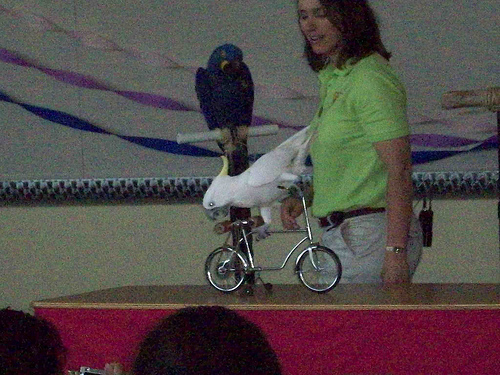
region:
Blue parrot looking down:
[191, 43, 259, 176]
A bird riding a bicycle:
[198, 121, 345, 296]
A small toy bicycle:
[206, 190, 345, 299]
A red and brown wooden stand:
[35, 281, 497, 371]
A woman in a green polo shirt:
[280, 1, 427, 282]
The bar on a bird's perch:
[173, 125, 285, 145]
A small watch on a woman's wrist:
[381, 241, 405, 256]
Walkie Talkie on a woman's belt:
[417, 192, 435, 249]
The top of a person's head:
[131, 303, 278, 373]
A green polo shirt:
[310, 58, 415, 221]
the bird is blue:
[213, 85, 232, 108]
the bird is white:
[243, 176, 271, 195]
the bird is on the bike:
[215, 179, 325, 260]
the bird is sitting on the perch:
[204, 106, 263, 143]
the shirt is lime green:
[321, 112, 364, 157]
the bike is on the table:
[217, 281, 345, 304]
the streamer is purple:
[113, 82, 149, 108]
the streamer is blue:
[116, 123, 163, 154]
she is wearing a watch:
[380, 240, 411, 260]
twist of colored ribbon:
[65, 16, 124, 57]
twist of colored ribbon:
[123, 38, 180, 77]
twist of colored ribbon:
[413, 108, 457, 133]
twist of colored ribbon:
[443, 109, 498, 139]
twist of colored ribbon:
[0, 42, 47, 75]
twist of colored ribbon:
[42, 56, 114, 99]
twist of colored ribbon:
[120, 82, 197, 124]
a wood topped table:
[28, 279, 495, 309]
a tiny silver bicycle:
[195, 172, 347, 296]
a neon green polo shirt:
[306, 69, 421, 216]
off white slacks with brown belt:
[301, 199, 428, 290]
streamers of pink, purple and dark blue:
[3, 0, 199, 162]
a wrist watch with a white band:
[381, 242, 408, 257]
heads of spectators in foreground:
[1, 297, 276, 373]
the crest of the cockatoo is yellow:
[208, 147, 236, 180]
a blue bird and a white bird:
[178, 33, 321, 250]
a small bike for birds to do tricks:
[202, 208, 351, 305]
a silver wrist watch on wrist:
[373, 243, 418, 263]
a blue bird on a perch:
[168, 41, 282, 159]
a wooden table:
[63, 265, 495, 316]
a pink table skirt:
[62, 305, 498, 368]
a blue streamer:
[6, 88, 173, 157]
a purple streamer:
[8, 49, 207, 124]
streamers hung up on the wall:
[26, 32, 187, 185]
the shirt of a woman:
[305, 61, 410, 209]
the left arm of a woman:
[348, 92, 419, 286]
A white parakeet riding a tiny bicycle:
[196, 115, 351, 300]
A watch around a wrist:
[375, 235, 412, 261]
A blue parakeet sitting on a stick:
[182, 30, 259, 182]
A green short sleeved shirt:
[300, 46, 416, 223]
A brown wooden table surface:
[26, 275, 496, 317]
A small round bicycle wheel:
[285, 237, 350, 297]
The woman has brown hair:
[290, 0, 397, 75]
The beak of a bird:
[197, 191, 237, 223]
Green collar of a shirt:
[310, 51, 360, 86]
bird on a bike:
[198, 109, 343, 299]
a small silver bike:
[200, 165, 348, 308]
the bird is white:
[188, 113, 323, 231]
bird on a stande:
[153, 32, 278, 159]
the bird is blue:
[180, 32, 259, 171]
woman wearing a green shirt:
[288, 49, 421, 226]